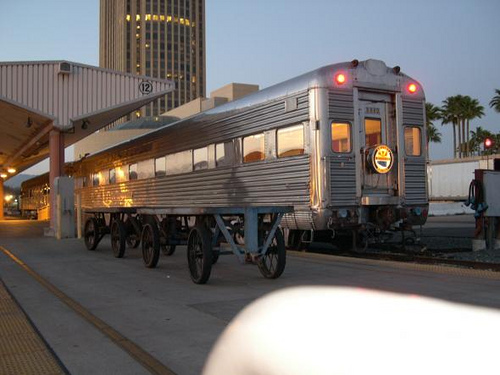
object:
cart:
[134, 205, 296, 286]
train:
[16, 58, 431, 252]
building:
[96, 0, 209, 135]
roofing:
[0, 59, 176, 187]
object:
[367, 144, 396, 175]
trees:
[457, 94, 489, 157]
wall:
[427, 153, 499, 202]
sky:
[0, 0, 500, 177]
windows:
[153, 154, 167, 178]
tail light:
[334, 71, 347, 86]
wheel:
[186, 225, 213, 286]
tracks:
[286, 250, 500, 276]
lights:
[6, 167, 17, 175]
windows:
[151, 32, 158, 41]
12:
[141, 82, 150, 92]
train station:
[1, 56, 500, 375]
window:
[330, 120, 353, 155]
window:
[275, 122, 305, 159]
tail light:
[407, 83, 418, 95]